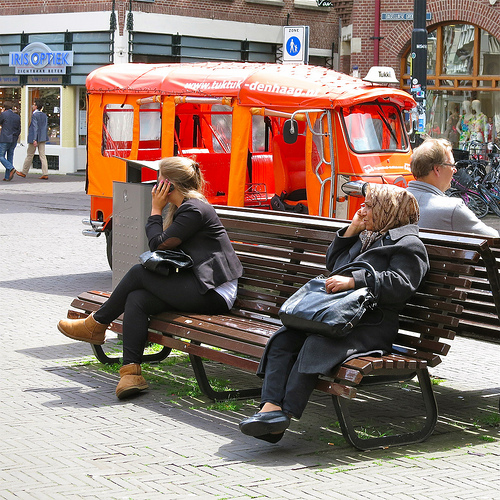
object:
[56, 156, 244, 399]
woman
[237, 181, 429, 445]
woman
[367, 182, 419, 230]
scarf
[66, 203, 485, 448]
bench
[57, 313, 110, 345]
boot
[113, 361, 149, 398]
boot